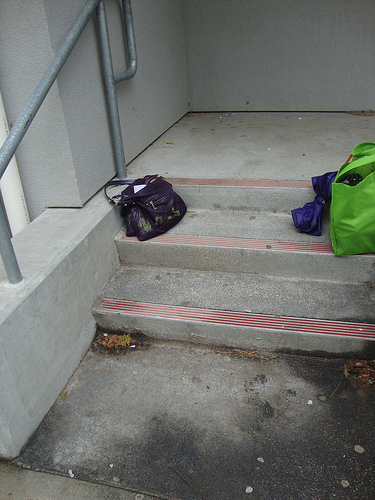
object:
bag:
[337, 173, 363, 186]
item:
[329, 142, 374, 256]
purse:
[99, 167, 189, 243]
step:
[114, 210, 370, 290]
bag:
[104, 171, 187, 242]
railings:
[0, 0, 142, 178]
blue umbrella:
[291, 169, 338, 237]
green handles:
[334, 142, 373, 182]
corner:
[95, 321, 106, 336]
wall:
[0, 0, 375, 211]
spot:
[114, 475, 122, 482]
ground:
[0, 329, 375, 500]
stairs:
[118, 174, 373, 258]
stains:
[139, 217, 152, 231]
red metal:
[97, 293, 375, 340]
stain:
[273, 442, 363, 490]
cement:
[0, 335, 374, 500]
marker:
[100, 293, 375, 341]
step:
[87, 258, 374, 364]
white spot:
[245, 486, 254, 493]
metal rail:
[0, 0, 138, 283]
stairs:
[124, 221, 336, 257]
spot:
[241, 483, 259, 494]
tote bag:
[329, 135, 374, 260]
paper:
[133, 184, 148, 194]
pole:
[90, 0, 134, 182]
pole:
[0, 196, 22, 283]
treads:
[93, 295, 375, 347]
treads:
[116, 228, 333, 255]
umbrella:
[288, 164, 336, 237]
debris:
[93, 332, 136, 349]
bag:
[329, 139, 375, 254]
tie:
[314, 193, 327, 204]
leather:
[103, 175, 186, 241]